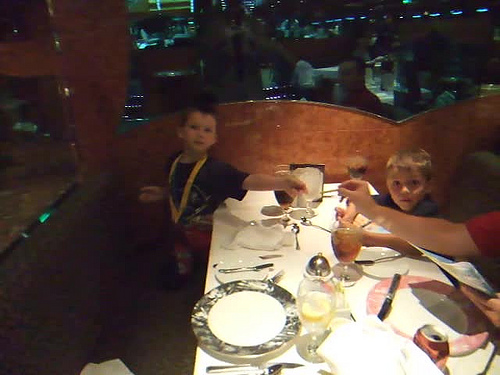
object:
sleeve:
[462, 210, 499, 259]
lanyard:
[168, 160, 206, 224]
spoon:
[300, 220, 331, 234]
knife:
[377, 273, 401, 321]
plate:
[367, 275, 493, 357]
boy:
[334, 147, 439, 258]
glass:
[331, 227, 363, 264]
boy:
[138, 107, 308, 290]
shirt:
[376, 192, 439, 216]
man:
[336, 57, 382, 114]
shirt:
[343, 88, 383, 114]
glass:
[297, 276, 338, 339]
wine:
[298, 276, 338, 334]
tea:
[331, 230, 361, 263]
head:
[176, 107, 217, 152]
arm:
[161, 186, 170, 198]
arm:
[220, 163, 283, 191]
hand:
[285, 174, 306, 198]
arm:
[376, 203, 499, 261]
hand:
[337, 178, 370, 205]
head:
[385, 146, 433, 211]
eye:
[412, 179, 420, 185]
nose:
[400, 184, 411, 195]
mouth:
[399, 197, 412, 202]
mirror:
[0, 2, 81, 255]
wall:
[78, 32, 124, 95]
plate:
[214, 256, 270, 284]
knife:
[219, 263, 274, 274]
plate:
[190, 280, 302, 359]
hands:
[334, 207, 353, 225]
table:
[217, 201, 255, 220]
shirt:
[163, 150, 251, 227]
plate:
[356, 246, 410, 278]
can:
[413, 324, 450, 373]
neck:
[182, 144, 206, 163]